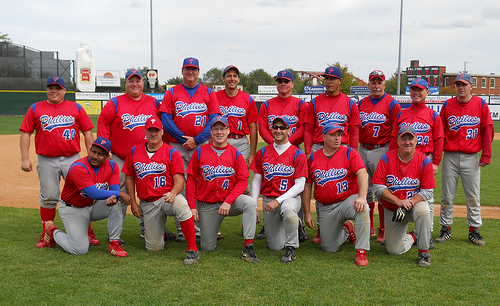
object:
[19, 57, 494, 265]
players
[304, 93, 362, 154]
uniform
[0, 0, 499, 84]
sky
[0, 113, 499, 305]
field